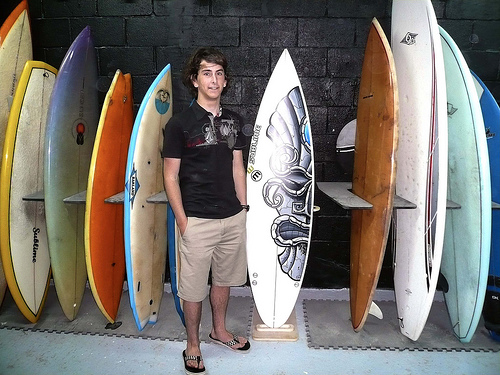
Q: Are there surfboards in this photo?
A: Yes, there is a surfboard.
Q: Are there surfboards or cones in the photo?
A: Yes, there is a surfboard.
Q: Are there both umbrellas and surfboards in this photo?
A: No, there is a surfboard but no umbrellas.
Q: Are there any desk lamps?
A: No, there are no desk lamps.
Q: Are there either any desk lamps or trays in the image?
A: No, there are no desk lamps or trays.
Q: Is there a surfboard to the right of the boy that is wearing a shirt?
A: Yes, there is a surfboard to the right of the boy.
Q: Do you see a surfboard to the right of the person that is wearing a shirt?
A: Yes, there is a surfboard to the right of the boy.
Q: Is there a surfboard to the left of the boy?
A: No, the surfboard is to the right of the boy.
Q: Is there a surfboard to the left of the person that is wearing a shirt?
A: No, the surfboard is to the right of the boy.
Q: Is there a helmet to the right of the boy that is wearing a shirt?
A: No, there is a surfboard to the right of the boy.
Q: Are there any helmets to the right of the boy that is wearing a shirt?
A: No, there is a surfboard to the right of the boy.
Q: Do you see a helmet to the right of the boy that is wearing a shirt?
A: No, there is a surfboard to the right of the boy.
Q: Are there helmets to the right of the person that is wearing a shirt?
A: No, there is a surfboard to the right of the boy.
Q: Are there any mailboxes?
A: No, there are no mailboxes.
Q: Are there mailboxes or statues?
A: No, there are no mailboxes or statues.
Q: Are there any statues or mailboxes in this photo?
A: No, there are no mailboxes or statues.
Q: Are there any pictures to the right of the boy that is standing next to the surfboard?
A: Yes, there is a picture to the right of the boy.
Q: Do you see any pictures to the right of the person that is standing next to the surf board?
A: Yes, there is a picture to the right of the boy.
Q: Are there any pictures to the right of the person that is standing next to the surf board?
A: Yes, there is a picture to the right of the boy.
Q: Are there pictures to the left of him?
A: No, the picture is to the right of the boy.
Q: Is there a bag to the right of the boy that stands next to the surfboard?
A: No, there is a picture to the right of the boy.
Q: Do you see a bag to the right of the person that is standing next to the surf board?
A: No, there is a picture to the right of the boy.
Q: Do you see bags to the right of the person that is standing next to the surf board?
A: No, there is a picture to the right of the boy.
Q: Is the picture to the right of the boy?
A: Yes, the picture is to the right of the boy.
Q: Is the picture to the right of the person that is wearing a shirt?
A: Yes, the picture is to the right of the boy.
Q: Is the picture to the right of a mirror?
A: No, the picture is to the right of the boy.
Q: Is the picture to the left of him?
A: No, the picture is to the right of the boy.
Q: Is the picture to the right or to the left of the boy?
A: The picture is to the right of the boy.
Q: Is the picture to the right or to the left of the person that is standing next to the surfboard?
A: The picture is to the right of the boy.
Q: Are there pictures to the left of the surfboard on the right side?
A: Yes, there is a picture to the left of the surfboard.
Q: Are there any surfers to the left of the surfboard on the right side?
A: No, there is a picture to the left of the surfboard.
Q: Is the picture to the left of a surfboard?
A: Yes, the picture is to the left of a surfboard.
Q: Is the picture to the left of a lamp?
A: No, the picture is to the left of a surfboard.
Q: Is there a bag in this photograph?
A: No, there are no bags.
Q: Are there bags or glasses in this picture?
A: No, there are no bags or glasses.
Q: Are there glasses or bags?
A: No, there are no bags or glasses.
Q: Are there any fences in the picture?
A: No, there are no fences.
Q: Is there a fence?
A: No, there are no fences.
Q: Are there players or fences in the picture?
A: No, there are no fences or players.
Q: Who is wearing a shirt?
A: The boy is wearing a shirt.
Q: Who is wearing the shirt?
A: The boy is wearing a shirt.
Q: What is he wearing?
A: The boy is wearing a shirt.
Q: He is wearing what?
A: The boy is wearing a shirt.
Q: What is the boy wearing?
A: The boy is wearing a shirt.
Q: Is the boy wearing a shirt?
A: Yes, the boy is wearing a shirt.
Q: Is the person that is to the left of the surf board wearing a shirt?
A: Yes, the boy is wearing a shirt.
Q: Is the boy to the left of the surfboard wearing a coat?
A: No, the boy is wearing a shirt.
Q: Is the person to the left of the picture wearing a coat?
A: No, the boy is wearing a shirt.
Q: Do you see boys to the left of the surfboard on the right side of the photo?
A: Yes, there is a boy to the left of the surf board.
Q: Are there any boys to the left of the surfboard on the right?
A: Yes, there is a boy to the left of the surf board.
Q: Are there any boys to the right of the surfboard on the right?
A: No, the boy is to the left of the surfboard.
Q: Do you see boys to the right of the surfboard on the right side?
A: No, the boy is to the left of the surfboard.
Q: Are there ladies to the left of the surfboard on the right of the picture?
A: No, there is a boy to the left of the surfboard.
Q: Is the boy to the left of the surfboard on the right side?
A: Yes, the boy is to the left of the surfboard.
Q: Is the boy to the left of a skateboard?
A: No, the boy is to the left of the surfboard.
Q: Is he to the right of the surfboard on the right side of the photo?
A: No, the boy is to the left of the surfboard.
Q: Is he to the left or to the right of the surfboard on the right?
A: The boy is to the left of the surf board.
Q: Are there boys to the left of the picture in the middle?
A: Yes, there is a boy to the left of the picture.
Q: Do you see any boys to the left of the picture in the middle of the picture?
A: Yes, there is a boy to the left of the picture.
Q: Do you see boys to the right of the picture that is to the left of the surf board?
A: No, the boy is to the left of the picture.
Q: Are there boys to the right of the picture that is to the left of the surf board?
A: No, the boy is to the left of the picture.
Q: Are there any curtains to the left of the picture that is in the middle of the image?
A: No, there is a boy to the left of the picture.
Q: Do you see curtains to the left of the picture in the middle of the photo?
A: No, there is a boy to the left of the picture.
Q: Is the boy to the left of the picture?
A: Yes, the boy is to the left of the picture.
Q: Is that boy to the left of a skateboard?
A: No, the boy is to the left of the picture.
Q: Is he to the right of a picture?
A: No, the boy is to the left of a picture.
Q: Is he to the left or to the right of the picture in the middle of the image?
A: The boy is to the left of the picture.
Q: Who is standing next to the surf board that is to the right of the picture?
A: The boy is standing next to the surfboard.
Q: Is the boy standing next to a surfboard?
A: Yes, the boy is standing next to a surfboard.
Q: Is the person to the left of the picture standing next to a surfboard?
A: Yes, the boy is standing next to a surfboard.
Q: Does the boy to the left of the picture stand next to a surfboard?
A: Yes, the boy stands next to a surfboard.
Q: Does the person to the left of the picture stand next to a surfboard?
A: Yes, the boy stands next to a surfboard.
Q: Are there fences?
A: No, there are no fences.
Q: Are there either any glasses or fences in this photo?
A: No, there are no fences or glasses.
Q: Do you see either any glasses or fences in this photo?
A: No, there are no fences or glasses.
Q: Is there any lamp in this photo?
A: No, there are no lamps.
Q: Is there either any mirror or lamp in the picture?
A: No, there are no lamps or mirrors.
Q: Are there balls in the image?
A: No, there are no balls.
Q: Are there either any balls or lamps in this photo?
A: No, there are no balls or lamps.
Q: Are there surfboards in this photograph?
A: Yes, there is a surfboard.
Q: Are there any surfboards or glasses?
A: Yes, there is a surfboard.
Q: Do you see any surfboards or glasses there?
A: Yes, there is a surfboard.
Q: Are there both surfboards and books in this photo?
A: No, there is a surfboard but no books.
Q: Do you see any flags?
A: No, there are no flags.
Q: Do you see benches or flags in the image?
A: No, there are no flags or benches.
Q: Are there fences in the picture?
A: No, there are no fences.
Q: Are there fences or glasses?
A: No, there are no fences or glasses.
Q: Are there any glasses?
A: No, there are no glasses.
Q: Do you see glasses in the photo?
A: No, there are no glasses.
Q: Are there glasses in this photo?
A: No, there are no glasses.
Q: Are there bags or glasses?
A: No, there are no glasses or bags.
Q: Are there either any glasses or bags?
A: No, there are no glasses or bags.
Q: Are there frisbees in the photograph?
A: No, there are no frisbees.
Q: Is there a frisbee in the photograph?
A: No, there are no frisbees.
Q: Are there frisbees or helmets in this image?
A: No, there are no frisbees or helmets.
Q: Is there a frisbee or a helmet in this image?
A: No, there are no frisbees or helmets.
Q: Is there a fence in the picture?
A: No, there are no fences.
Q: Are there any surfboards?
A: Yes, there is a surfboard.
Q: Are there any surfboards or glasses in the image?
A: Yes, there is a surfboard.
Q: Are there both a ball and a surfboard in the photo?
A: No, there is a surfboard but no balls.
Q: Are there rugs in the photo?
A: No, there are no rugs.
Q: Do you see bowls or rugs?
A: No, there are no rugs or bowls.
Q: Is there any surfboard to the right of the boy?
A: Yes, there is a surfboard to the right of the boy.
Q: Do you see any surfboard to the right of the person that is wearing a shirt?
A: Yes, there is a surfboard to the right of the boy.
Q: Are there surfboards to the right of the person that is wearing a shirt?
A: Yes, there is a surfboard to the right of the boy.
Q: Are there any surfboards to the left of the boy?
A: No, the surfboard is to the right of the boy.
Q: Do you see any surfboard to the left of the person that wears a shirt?
A: No, the surfboard is to the right of the boy.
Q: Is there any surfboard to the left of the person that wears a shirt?
A: No, the surfboard is to the right of the boy.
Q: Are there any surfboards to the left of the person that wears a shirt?
A: No, the surfboard is to the right of the boy.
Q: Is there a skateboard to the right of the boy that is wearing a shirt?
A: No, there is a surfboard to the right of the boy.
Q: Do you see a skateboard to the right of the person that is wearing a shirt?
A: No, there is a surfboard to the right of the boy.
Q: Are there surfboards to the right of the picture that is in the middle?
A: Yes, there is a surfboard to the right of the picture.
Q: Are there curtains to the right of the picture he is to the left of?
A: No, there is a surfboard to the right of the picture.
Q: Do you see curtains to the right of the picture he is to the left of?
A: No, there is a surfboard to the right of the picture.